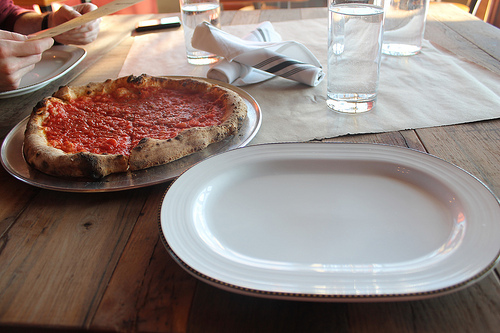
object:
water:
[328, 7, 380, 110]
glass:
[181, 0, 216, 65]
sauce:
[40, 86, 233, 151]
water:
[376, 7, 426, 57]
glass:
[377, 0, 427, 57]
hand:
[1, 28, 58, 92]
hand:
[51, 3, 102, 45]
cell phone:
[135, 17, 181, 31]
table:
[0, 0, 499, 333]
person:
[2, 1, 97, 90]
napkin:
[190, 21, 323, 88]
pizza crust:
[16, 73, 249, 179]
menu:
[27, 0, 146, 41]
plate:
[155, 142, 498, 301]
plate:
[0, 73, 263, 194]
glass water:
[182, 5, 220, 63]